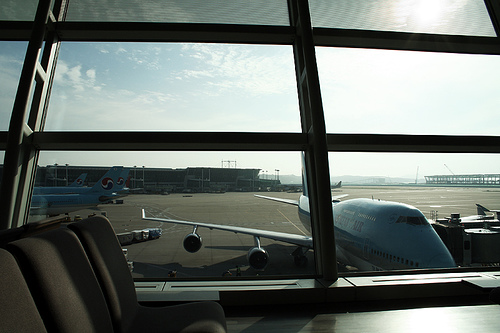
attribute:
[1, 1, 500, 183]
sky — cloudy, foggy, bright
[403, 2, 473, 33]
sun — bright, glowing, shining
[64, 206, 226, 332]
chairs — brown, inside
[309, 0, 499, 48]
window — overlooking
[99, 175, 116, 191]
circle — red, blue, pepsi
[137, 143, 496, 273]
plane — parked, blue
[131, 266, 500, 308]
table — long, wooden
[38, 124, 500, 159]
ledge — gray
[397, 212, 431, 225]
windshield — cockpit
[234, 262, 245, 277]
man — working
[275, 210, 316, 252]
line — painted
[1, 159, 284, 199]
building — on side